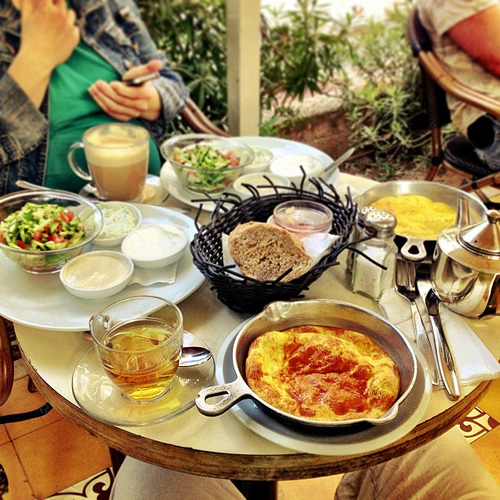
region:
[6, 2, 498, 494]
the lady is setting at a table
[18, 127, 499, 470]
the table is full of food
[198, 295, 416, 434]
an iron skillet has an egg concoction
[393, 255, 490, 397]
a knife and fork are on a napkin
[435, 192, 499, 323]
a silver pot is on the table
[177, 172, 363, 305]
a black wicker basket has bread in it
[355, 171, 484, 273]
cooked eggs are in a skillet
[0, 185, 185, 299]
a salad has three kinds of dip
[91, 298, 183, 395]
a glass cup has tea in it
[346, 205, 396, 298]
salt and pepper shakers are on the table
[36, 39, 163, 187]
woman's shirt is green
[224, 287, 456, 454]
silver pan on plate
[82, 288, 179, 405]
glass of liquid on table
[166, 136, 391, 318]
the basket is black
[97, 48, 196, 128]
woman holding a phone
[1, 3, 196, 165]
woman wearing jean jacket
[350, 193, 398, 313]
salt and pepper next to pan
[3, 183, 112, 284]
salad in the bowl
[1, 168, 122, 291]
the bowl is clear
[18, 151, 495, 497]
the table is white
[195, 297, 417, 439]
pizza in a skillet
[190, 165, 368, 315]
a black basket of bread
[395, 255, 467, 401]
a silver knife and fork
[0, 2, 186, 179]
a woman holding a cellphone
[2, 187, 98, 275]
a clear bowl of salad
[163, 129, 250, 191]
a clear bowl of salad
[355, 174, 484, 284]
a skillet of eggs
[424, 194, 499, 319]
a syrup container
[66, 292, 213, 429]
a clear glass of tea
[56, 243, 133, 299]
a white bowl of dressing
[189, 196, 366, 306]
black basket holding bread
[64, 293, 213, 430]
clear glass cup and saucer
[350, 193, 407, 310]
salt and pepper shakers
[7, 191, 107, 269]
bowl of green salad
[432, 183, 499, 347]
silver teapot on table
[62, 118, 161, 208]
cup of hot coffee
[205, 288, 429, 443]
iron frying pan on round pan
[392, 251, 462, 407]
fork and knife on napkin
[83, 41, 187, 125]
person holding cell phone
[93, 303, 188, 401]
cup of hot tea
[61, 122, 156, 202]
A coffee drink.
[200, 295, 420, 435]
Food cooked in a cast-iron skillet.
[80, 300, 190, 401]
A cup of tea.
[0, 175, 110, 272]
A salad in a small glass bowl.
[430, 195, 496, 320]
A metal tea kettle.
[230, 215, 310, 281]
Bread.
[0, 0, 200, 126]
The person is looking at a cellphone.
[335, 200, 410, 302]
A salt and pepper shaker.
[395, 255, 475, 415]
Silverware on top of a napkin.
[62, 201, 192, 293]
Three small condiment bowls.